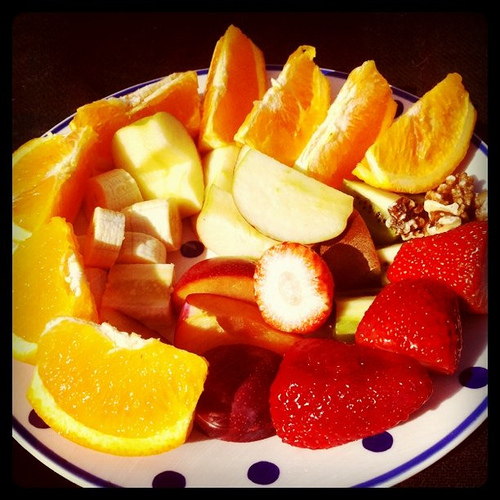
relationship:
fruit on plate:
[10, 20, 497, 465] [13, 54, 494, 490]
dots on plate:
[242, 453, 282, 489] [13, 54, 494, 490]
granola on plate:
[384, 167, 489, 247] [13, 54, 494, 490]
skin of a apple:
[193, 343, 279, 440] [190, 343, 280, 439]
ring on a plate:
[12, 67, 498, 487] [13, 54, 494, 490]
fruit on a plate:
[10, 20, 497, 465] [13, 54, 494, 490]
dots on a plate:
[247, 461, 278, 486] [13, 54, 494, 490]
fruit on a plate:
[29, 317, 208, 465] [13, 54, 494, 490]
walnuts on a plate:
[382, 168, 486, 242] [13, 54, 494, 490]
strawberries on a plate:
[269, 218, 489, 449] [13, 54, 494, 490]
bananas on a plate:
[82, 170, 182, 266] [13, 54, 494, 490]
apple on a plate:
[112, 112, 354, 264] [13, 54, 494, 490]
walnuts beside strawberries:
[382, 168, 486, 242] [269, 218, 489, 449]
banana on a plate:
[82, 208, 122, 268] [13, 54, 494, 490]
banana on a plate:
[115, 230, 166, 264] [13, 54, 494, 490]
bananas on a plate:
[117, 198, 182, 253] [13, 54, 494, 490]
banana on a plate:
[88, 166, 141, 211] [13, 54, 494, 490]